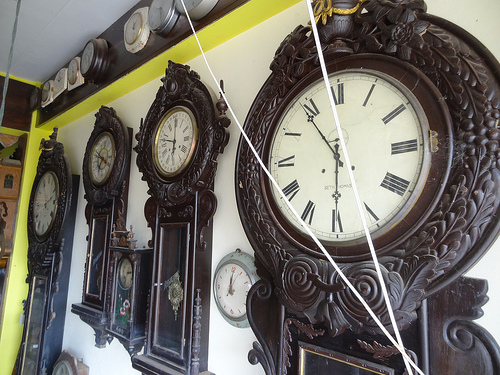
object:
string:
[178, 0, 429, 375]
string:
[307, 0, 410, 375]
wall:
[0, 1, 499, 375]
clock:
[144, 1, 184, 36]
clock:
[120, 5, 154, 55]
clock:
[76, 36, 111, 79]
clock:
[62, 55, 87, 90]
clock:
[232, 1, 498, 375]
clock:
[127, 54, 235, 375]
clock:
[72, 99, 139, 352]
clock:
[16, 122, 80, 375]